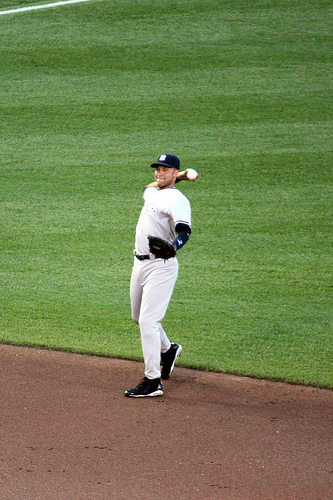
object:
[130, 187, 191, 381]
uniform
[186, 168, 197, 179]
ball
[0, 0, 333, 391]
field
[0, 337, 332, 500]
ground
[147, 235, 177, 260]
baseball glove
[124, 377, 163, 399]
shoe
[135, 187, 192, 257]
jersey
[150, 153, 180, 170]
cap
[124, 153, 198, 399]
man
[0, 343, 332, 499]
dirt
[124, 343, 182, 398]
cleats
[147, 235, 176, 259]
hand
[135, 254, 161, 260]
belt